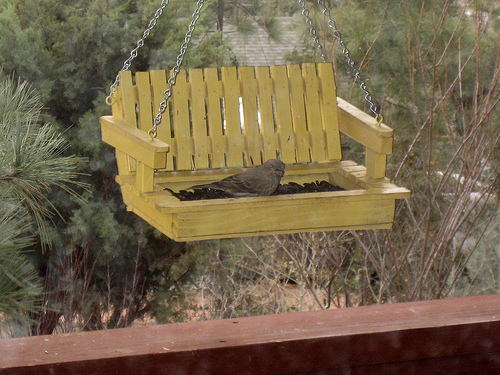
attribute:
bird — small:
[183, 157, 286, 197]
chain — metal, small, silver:
[296, 0, 328, 64]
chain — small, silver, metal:
[110, 0, 168, 90]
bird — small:
[189, 156, 293, 201]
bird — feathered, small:
[178, 153, 305, 201]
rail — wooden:
[0, 294, 498, 374]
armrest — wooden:
[319, 87, 424, 165]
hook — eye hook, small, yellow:
[142, 117, 176, 157]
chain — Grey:
[291, 9, 406, 135]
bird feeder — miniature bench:
[125, 157, 384, 235]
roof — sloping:
[190, 15, 318, 68]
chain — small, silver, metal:
[147, 0, 204, 138]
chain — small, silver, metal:
[318, 0, 378, 116]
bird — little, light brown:
[192, 151, 294, 203]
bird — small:
[177, 155, 287, 199]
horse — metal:
[336, 10, 369, 87]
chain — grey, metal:
[141, 0, 202, 151]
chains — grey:
[121, 15, 210, 125]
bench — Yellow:
[105, 15, 420, 247]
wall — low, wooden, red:
[1, 290, 499, 373]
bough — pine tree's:
[1, 67, 94, 337]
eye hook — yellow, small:
[373, 115, 385, 126]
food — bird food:
[296, 176, 324, 191]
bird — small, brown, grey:
[184, 154, 306, 210]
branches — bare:
[289, 212, 449, 283]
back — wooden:
[122, 56, 342, 164]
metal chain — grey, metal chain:
[91, 5, 381, 77]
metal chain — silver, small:
[314, 0, 390, 131]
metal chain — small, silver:
[295, 0, 327, 66]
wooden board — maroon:
[0, 293, 499, 374]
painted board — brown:
[338, 309, 479, 362]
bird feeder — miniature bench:
[99, 56, 411, 247]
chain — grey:
[306, 4, 396, 111]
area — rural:
[1, 4, 494, 372]